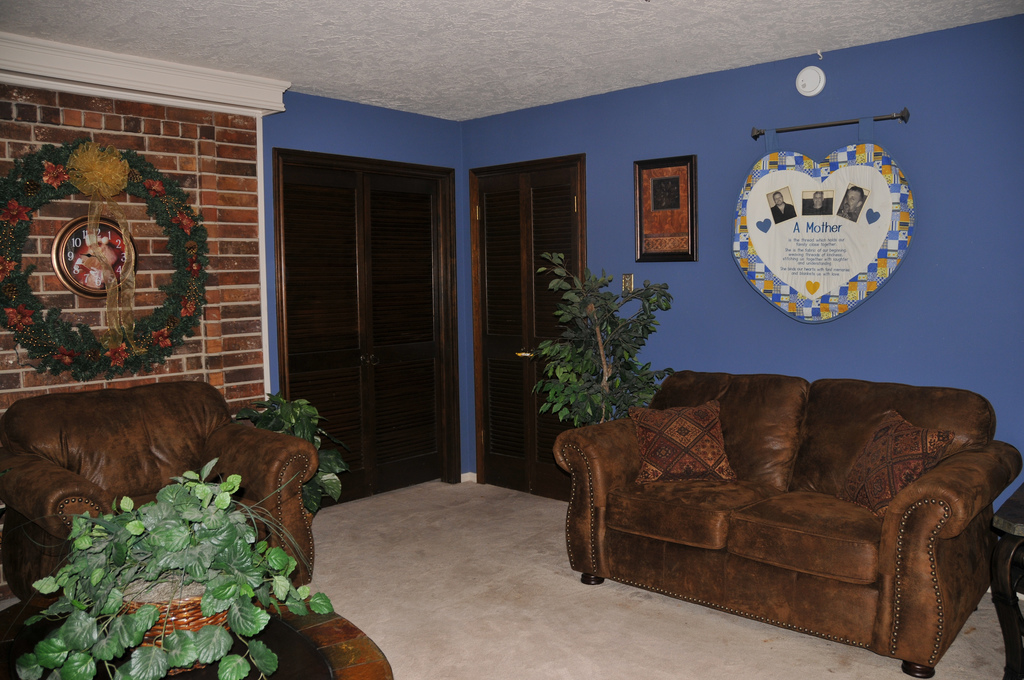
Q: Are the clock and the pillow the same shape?
A: No, the clock is round and the pillow is square.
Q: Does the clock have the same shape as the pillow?
A: No, the clock is round and the pillow is square.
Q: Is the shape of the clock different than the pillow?
A: Yes, the clock is round and the pillow is square.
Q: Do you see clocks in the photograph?
A: Yes, there is a clock.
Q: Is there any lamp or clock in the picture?
A: Yes, there is a clock.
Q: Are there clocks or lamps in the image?
A: Yes, there is a clock.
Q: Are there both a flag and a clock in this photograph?
A: No, there is a clock but no flags.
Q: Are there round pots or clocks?
A: Yes, there is a round clock.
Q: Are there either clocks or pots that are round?
A: Yes, the clock is round.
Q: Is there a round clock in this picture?
A: Yes, there is a round clock.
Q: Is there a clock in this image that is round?
A: Yes, there is a clock that is round.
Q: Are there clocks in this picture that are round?
A: Yes, there is a clock that is round.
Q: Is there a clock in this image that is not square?
A: Yes, there is a round clock.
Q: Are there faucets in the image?
A: No, there are no faucets.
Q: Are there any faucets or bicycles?
A: No, there are no faucets or bicycles.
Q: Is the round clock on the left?
A: Yes, the clock is on the left of the image.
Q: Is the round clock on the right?
A: No, the clock is on the left of the image.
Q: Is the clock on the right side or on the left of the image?
A: The clock is on the left of the image.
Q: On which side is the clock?
A: The clock is on the left of the image.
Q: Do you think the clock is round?
A: Yes, the clock is round.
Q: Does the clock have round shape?
A: Yes, the clock is round.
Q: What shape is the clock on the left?
A: The clock is round.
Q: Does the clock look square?
A: No, the clock is round.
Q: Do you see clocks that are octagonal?
A: No, there is a clock but it is round.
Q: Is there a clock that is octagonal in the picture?
A: No, there is a clock but it is round.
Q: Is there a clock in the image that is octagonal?
A: No, there is a clock but it is round.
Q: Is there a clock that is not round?
A: No, there is a clock but it is round.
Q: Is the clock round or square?
A: The clock is round.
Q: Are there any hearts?
A: Yes, there is a heart.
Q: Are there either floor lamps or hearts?
A: Yes, there is a heart.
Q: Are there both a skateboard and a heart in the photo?
A: No, there is a heart but no skateboards.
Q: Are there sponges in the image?
A: No, there are no sponges.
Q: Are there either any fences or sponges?
A: No, there are no sponges or fences.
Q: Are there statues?
A: No, there are no statues.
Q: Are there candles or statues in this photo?
A: No, there are no statues or candles.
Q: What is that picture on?
A: The picture is on the wall.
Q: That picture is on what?
A: The picture is on the wall.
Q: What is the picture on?
A: The picture is on the wall.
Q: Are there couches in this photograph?
A: Yes, there is a couch.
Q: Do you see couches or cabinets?
A: Yes, there is a couch.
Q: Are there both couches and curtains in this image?
A: No, there is a couch but no curtains.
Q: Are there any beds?
A: No, there are no beds.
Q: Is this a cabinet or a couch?
A: This is a couch.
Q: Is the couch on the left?
A: No, the couch is on the right of the image.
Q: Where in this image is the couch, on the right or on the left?
A: The couch is on the right of the image.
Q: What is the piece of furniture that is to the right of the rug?
A: The piece of furniture is a couch.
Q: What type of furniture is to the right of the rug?
A: The piece of furniture is a couch.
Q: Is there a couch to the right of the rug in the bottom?
A: Yes, there is a couch to the right of the rug.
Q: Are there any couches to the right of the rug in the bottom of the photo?
A: Yes, there is a couch to the right of the rug.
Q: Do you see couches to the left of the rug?
A: No, the couch is to the right of the rug.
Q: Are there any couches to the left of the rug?
A: No, the couch is to the right of the rug.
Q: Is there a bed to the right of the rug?
A: No, there is a couch to the right of the rug.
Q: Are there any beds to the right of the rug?
A: No, there is a couch to the right of the rug.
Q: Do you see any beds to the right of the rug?
A: No, there is a couch to the right of the rug.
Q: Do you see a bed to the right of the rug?
A: No, there is a couch to the right of the rug.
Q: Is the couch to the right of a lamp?
A: No, the couch is to the right of the rug.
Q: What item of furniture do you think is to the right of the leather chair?
A: The piece of furniture is a couch.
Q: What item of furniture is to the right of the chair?
A: The piece of furniture is a couch.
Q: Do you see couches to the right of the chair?
A: Yes, there is a couch to the right of the chair.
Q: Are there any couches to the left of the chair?
A: No, the couch is to the right of the chair.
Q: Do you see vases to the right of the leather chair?
A: No, there is a couch to the right of the chair.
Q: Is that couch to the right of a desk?
A: No, the couch is to the right of the chair.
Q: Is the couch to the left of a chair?
A: No, the couch is to the right of a chair.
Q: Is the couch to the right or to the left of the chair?
A: The couch is to the right of the chair.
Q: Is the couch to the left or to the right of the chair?
A: The couch is to the right of the chair.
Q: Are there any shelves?
A: No, there are no shelves.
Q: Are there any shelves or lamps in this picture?
A: No, there are no shelves or lamps.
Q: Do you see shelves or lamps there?
A: No, there are no shelves or lamps.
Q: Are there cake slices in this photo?
A: No, there are no cake slices.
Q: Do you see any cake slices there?
A: No, there are no cake slices.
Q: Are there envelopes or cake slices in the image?
A: No, there are no cake slices or envelopes.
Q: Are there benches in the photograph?
A: No, there are no benches.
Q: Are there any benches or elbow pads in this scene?
A: No, there are no benches or elbow pads.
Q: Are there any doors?
A: Yes, there is a door.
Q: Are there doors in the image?
A: Yes, there is a door.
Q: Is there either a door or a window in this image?
A: Yes, there is a door.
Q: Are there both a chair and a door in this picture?
A: Yes, there are both a door and a chair.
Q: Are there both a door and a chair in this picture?
A: Yes, there are both a door and a chair.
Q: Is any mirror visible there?
A: No, there are no mirrors.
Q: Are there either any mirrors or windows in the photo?
A: No, there are no mirrors or windows.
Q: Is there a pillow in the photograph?
A: Yes, there is a pillow.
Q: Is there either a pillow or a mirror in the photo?
A: Yes, there is a pillow.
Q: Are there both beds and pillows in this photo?
A: No, there is a pillow but no beds.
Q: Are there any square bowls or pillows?
A: Yes, there is a square pillow.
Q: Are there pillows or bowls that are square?
A: Yes, the pillow is square.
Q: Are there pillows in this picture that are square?
A: Yes, there is a square pillow.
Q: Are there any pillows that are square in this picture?
A: Yes, there is a square pillow.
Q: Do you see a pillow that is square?
A: Yes, there is a pillow that is square.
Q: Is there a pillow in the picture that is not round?
A: Yes, there is a square pillow.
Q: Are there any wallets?
A: No, there are no wallets.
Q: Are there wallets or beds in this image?
A: No, there are no wallets or beds.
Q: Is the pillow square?
A: Yes, the pillow is square.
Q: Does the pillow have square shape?
A: Yes, the pillow is square.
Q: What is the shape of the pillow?
A: The pillow is square.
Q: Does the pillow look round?
A: No, the pillow is square.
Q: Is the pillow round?
A: No, the pillow is square.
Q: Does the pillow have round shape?
A: No, the pillow is square.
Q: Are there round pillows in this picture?
A: No, there is a pillow but it is square.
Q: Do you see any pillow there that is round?
A: No, there is a pillow but it is square.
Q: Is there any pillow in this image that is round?
A: No, there is a pillow but it is square.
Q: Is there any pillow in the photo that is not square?
A: No, there is a pillow but it is square.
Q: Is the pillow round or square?
A: The pillow is square.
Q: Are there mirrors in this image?
A: No, there are no mirrors.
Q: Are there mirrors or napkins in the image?
A: No, there are no mirrors or napkins.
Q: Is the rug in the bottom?
A: Yes, the rug is in the bottom of the image.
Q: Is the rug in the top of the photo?
A: No, the rug is in the bottom of the image.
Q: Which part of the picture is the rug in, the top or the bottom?
A: The rug is in the bottom of the image.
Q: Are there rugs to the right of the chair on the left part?
A: Yes, there is a rug to the right of the chair.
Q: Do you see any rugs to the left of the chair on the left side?
A: No, the rug is to the right of the chair.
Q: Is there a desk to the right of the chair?
A: No, there is a rug to the right of the chair.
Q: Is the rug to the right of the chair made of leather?
A: Yes, the rug is to the right of the chair.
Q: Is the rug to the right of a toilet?
A: No, the rug is to the right of the chair.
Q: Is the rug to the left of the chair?
A: No, the rug is to the right of the chair.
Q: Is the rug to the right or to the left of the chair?
A: The rug is to the right of the chair.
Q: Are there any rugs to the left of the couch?
A: Yes, there is a rug to the left of the couch.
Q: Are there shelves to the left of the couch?
A: No, there is a rug to the left of the couch.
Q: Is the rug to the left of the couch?
A: Yes, the rug is to the left of the couch.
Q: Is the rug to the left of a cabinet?
A: No, the rug is to the left of the couch.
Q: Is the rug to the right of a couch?
A: No, the rug is to the left of a couch.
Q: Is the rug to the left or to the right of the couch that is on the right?
A: The rug is to the left of the couch.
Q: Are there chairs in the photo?
A: Yes, there is a chair.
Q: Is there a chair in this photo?
A: Yes, there is a chair.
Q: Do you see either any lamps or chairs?
A: Yes, there is a chair.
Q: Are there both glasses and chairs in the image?
A: No, there is a chair but no glasses.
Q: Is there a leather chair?
A: Yes, there is a chair that is made of leather.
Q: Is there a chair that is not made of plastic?
A: Yes, there is a chair that is made of leather.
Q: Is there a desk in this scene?
A: No, there are no desks.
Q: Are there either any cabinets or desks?
A: No, there are no desks or cabinets.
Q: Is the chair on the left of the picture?
A: Yes, the chair is on the left of the image.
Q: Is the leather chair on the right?
A: No, the chair is on the left of the image.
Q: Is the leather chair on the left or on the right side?
A: The chair is on the left of the image.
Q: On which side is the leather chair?
A: The chair is on the left of the image.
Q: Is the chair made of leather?
A: Yes, the chair is made of leather.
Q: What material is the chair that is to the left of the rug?
A: The chair is made of leather.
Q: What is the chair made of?
A: The chair is made of leather.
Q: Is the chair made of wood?
A: No, the chair is made of leather.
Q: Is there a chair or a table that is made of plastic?
A: No, there is a chair but it is made of leather.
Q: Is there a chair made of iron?
A: No, there is a chair but it is made of leather.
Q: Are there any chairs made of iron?
A: No, there is a chair but it is made of leather.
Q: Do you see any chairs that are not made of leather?
A: No, there is a chair but it is made of leather.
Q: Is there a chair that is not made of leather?
A: No, there is a chair but it is made of leather.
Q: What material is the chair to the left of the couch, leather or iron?
A: The chair is made of leather.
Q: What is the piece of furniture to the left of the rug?
A: The piece of furniture is a chair.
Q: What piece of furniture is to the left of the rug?
A: The piece of furniture is a chair.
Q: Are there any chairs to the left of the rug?
A: Yes, there is a chair to the left of the rug.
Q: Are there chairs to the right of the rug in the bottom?
A: No, the chair is to the left of the rug.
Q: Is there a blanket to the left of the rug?
A: No, there is a chair to the left of the rug.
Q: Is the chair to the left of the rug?
A: Yes, the chair is to the left of the rug.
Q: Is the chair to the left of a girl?
A: No, the chair is to the left of the rug.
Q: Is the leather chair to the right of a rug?
A: No, the chair is to the left of a rug.